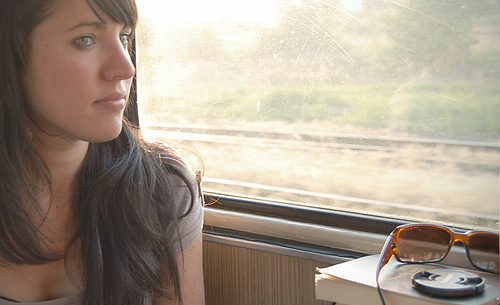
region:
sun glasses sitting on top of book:
[368, 210, 497, 304]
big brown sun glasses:
[373, 210, 498, 303]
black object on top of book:
[408, 257, 483, 304]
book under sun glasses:
[306, 245, 498, 302]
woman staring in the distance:
[0, 2, 211, 304]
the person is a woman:
[1, 0, 227, 303]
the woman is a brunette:
[0, 1, 225, 303]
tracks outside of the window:
[143, 115, 495, 187]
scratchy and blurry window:
[134, 3, 499, 231]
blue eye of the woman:
[73, 28, 100, 53]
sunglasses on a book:
[363, 214, 494, 298]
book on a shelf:
[308, 247, 496, 304]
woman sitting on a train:
[8, 4, 250, 303]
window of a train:
[200, 17, 451, 184]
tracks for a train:
[175, 119, 405, 167]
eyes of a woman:
[70, 14, 145, 54]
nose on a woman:
[96, 31, 137, 86]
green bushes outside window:
[254, 82, 469, 134]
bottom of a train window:
[220, 203, 346, 258]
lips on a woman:
[88, 82, 136, 116]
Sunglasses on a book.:
[380, 223, 498, 304]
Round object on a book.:
[411, 264, 487, 298]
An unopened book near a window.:
[311, 253, 498, 303]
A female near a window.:
[2, 1, 222, 303]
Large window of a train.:
[135, 0, 498, 242]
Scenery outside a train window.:
[138, 0, 498, 216]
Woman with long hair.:
[2, 3, 204, 302]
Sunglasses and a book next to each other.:
[314, 220, 499, 302]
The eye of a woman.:
[69, 29, 99, 50]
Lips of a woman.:
[91, 88, 131, 112]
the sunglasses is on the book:
[354, 216, 499, 302]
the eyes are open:
[41, 25, 141, 60]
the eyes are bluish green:
[60, 21, 145, 61]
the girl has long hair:
[10, 0, 209, 295]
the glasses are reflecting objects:
[376, 213, 452, 264]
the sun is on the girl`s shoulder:
[107, 90, 219, 202]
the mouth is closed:
[80, 77, 133, 118]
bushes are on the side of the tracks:
[221, 58, 493, 156]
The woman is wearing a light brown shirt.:
[1, 0, 203, 304]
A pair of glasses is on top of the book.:
[315, 218, 499, 302]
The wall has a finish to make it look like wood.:
[201, 240, 330, 303]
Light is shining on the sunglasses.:
[375, 221, 497, 303]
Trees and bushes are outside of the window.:
[138, 3, 498, 138]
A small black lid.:
[410, 266, 485, 297]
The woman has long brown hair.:
[0, 0, 203, 302]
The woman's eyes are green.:
[72, 33, 127, 49]